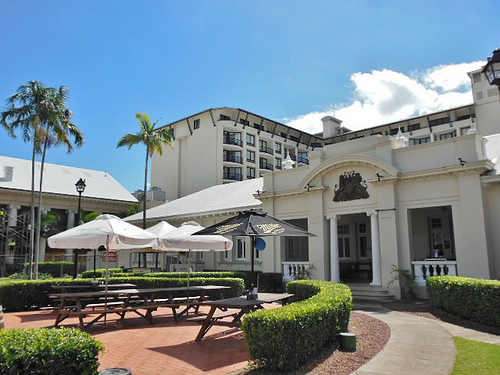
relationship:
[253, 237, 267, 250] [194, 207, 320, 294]
balloon under umbrella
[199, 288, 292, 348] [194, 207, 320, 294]
table has umbrella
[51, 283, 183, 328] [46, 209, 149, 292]
table has umbrella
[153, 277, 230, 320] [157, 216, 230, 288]
table has umbrella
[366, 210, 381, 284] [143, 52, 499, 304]
column on building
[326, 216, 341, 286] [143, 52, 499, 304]
column on building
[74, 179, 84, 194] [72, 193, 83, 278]
lamp on post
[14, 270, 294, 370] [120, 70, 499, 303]
shade outside of building